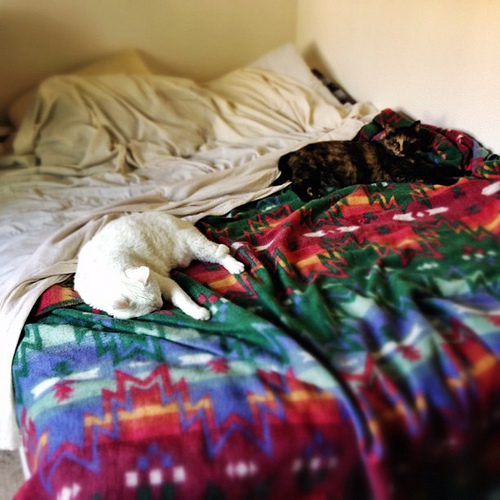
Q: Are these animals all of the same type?
A: Yes, all the animals are cats.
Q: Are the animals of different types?
A: No, all the animals are cats.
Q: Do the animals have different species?
A: No, all the animals are cats.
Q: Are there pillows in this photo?
A: Yes, there are pillows.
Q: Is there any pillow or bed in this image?
A: Yes, there are pillows.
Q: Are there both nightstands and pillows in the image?
A: No, there are pillows but no nightstands.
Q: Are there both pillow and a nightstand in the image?
A: No, there are pillows but no nightstands.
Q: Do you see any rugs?
A: No, there are no rugs.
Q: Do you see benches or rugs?
A: No, there are no rugs or benches.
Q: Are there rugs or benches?
A: No, there are no rugs or benches.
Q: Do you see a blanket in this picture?
A: Yes, there is a blanket.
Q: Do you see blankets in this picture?
A: Yes, there is a blanket.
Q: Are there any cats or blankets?
A: Yes, there is a blanket.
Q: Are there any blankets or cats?
A: Yes, there is a blanket.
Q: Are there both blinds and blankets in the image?
A: No, there is a blanket but no blinds.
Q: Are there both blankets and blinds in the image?
A: No, there is a blanket but no blinds.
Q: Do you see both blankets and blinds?
A: No, there is a blanket but no blinds.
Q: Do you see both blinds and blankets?
A: No, there is a blanket but no blinds.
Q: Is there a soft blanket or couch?
A: Yes, there is a soft blanket.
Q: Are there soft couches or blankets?
A: Yes, there is a soft blanket.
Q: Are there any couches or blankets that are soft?
A: Yes, the blanket is soft.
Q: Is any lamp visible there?
A: No, there are no lamps.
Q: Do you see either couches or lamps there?
A: No, there are no lamps or couches.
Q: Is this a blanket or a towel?
A: This is a blanket.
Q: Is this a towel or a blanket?
A: This is a blanket.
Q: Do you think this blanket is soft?
A: Yes, the blanket is soft.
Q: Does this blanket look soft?
A: Yes, the blanket is soft.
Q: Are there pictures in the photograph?
A: No, there are no pictures.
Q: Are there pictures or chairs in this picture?
A: No, there are no pictures or chairs.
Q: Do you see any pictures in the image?
A: No, there are no pictures.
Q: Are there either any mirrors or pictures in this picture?
A: No, there are no pictures or mirrors.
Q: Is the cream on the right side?
A: Yes, the cream is on the right of the image.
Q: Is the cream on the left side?
A: No, the cream is on the right of the image.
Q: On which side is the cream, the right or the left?
A: The cream is on the right of the image.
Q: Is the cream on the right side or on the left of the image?
A: The cream is on the right of the image.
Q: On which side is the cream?
A: The cream is on the right of the image.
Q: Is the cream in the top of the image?
A: Yes, the cream is in the top of the image.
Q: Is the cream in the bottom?
A: No, the cream is in the top of the image.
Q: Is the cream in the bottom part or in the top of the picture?
A: The cream is in the top of the image.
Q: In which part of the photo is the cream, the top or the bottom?
A: The cream is in the top of the image.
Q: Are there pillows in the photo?
A: Yes, there is a pillow.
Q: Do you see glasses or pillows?
A: Yes, there is a pillow.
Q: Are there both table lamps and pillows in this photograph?
A: No, there is a pillow but no table lamps.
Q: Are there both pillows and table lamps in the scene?
A: No, there is a pillow but no table lamps.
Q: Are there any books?
A: No, there are no books.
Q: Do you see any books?
A: No, there are no books.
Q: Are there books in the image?
A: No, there are no books.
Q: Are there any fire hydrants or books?
A: No, there are no books or fire hydrants.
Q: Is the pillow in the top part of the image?
A: Yes, the pillow is in the top of the image.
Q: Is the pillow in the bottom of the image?
A: No, the pillow is in the top of the image.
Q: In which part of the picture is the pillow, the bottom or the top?
A: The pillow is in the top of the image.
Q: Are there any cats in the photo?
A: Yes, there is a cat.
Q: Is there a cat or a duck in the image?
A: Yes, there is a cat.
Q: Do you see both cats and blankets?
A: Yes, there are both a cat and a blanket.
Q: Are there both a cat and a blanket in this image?
A: Yes, there are both a cat and a blanket.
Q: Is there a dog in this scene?
A: No, there are no dogs.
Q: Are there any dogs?
A: No, there are no dogs.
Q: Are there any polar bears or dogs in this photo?
A: No, there are no dogs or polar bears.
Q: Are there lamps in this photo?
A: No, there are no lamps.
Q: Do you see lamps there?
A: No, there are no lamps.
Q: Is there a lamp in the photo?
A: No, there are no lamps.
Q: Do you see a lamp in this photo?
A: No, there are no lamps.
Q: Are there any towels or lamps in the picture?
A: No, there are no lamps or towels.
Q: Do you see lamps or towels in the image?
A: No, there are no lamps or towels.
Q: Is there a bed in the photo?
A: Yes, there is a bed.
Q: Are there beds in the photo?
A: Yes, there is a bed.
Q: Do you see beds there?
A: Yes, there is a bed.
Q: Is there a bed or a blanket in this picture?
A: Yes, there is a bed.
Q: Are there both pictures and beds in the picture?
A: No, there is a bed but no pictures.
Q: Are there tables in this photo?
A: No, there are no tables.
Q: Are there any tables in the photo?
A: No, there are no tables.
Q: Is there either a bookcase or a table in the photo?
A: No, there are no tables or bookcases.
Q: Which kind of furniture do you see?
A: The furniture is a bed.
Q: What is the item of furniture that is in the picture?
A: The piece of furniture is a bed.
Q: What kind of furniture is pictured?
A: The furniture is a bed.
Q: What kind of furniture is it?
A: The piece of furniture is a bed.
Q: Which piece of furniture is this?
A: This is a bed.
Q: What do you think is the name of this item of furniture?
A: This is a bed.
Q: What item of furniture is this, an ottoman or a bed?
A: This is a bed.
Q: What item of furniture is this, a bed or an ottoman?
A: This is a bed.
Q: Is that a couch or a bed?
A: That is a bed.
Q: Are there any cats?
A: Yes, there are cats.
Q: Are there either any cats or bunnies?
A: Yes, there are cats.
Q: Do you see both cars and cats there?
A: No, there are cats but no cars.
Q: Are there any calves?
A: No, there are no calves.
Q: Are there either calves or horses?
A: No, there are no calves or horses.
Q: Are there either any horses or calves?
A: No, there are no calves or horses.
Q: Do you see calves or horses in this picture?
A: No, there are no calves or horses.